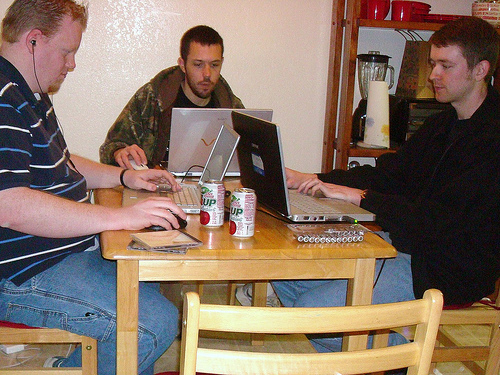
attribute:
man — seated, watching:
[0, 0, 183, 373]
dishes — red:
[412, 0, 472, 25]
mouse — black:
[133, 191, 197, 236]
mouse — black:
[121, 147, 153, 173]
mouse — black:
[133, 204, 185, 225]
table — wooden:
[82, 153, 391, 291]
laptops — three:
[119, 103, 379, 225]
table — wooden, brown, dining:
[94, 176, 396, 373]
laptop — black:
[229, 108, 377, 227]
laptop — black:
[227, 107, 387, 231]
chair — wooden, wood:
[178, 286, 448, 371]